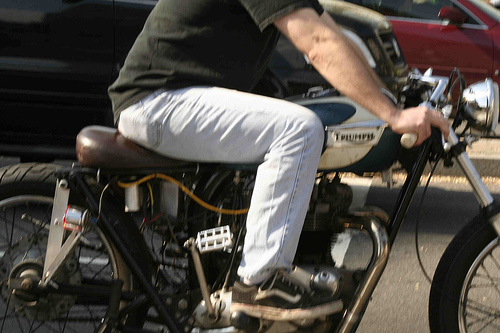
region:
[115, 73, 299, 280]
human wearing pants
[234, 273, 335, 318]
dirty shoes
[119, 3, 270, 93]
human wearing black shirt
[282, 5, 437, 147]
hands on handles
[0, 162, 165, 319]
back tire for driving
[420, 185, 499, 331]
front tire for driving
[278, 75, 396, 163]
motor of some sort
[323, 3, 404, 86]
front of vehicle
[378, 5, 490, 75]
smaller red vehicle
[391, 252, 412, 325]
asphalt for smooth drives/walks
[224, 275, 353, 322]
Man wearing shoes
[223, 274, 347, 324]
Man is wearing shoes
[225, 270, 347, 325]
Man wearing black and white shoes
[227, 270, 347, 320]
Man is wearing black and white shoes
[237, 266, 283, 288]
Man wearing socks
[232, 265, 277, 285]
Man is wearing socks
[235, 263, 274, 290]
Man wearing white socks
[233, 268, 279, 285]
Man is wearing white socks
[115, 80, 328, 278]
Man wearing pants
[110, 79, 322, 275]
Man is wearing pants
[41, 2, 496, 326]
a man in a black shirt and some jeans riding a motorcycle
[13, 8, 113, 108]
a black door from a truck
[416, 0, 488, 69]
a red car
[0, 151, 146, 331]
rear motorcycle tire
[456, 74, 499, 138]
motorcycle head light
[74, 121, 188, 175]
a motorcycle seat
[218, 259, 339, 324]
some black shoes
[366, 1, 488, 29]
a window of a red car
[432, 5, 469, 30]
a side view mirror on a red car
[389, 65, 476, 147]
a motorcycle steering wheel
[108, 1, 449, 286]
man riding motor bike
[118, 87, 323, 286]
white pants worn by the man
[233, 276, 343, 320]
black and white tennis shoe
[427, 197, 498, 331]
front wheel of bike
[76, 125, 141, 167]
brown seat if bike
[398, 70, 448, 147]
handlebar of the bike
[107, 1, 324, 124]
black tee shirt man is wearing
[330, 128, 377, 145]
black print on white background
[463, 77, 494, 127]
headlight of the bike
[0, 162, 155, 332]
back wheel of bike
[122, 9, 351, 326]
A man on a motorcycle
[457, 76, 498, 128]
A front touch of a motor cycle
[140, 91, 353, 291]
A man's blue jeans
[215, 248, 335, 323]
A black and white shoe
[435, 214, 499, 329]
A front wheel of a bike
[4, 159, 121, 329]
A back wheel of a bike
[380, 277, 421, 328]
A grey tarmac road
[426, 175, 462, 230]
A grey tarmac road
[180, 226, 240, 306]
A white silver pedal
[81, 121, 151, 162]
A brown motor ciycle seat